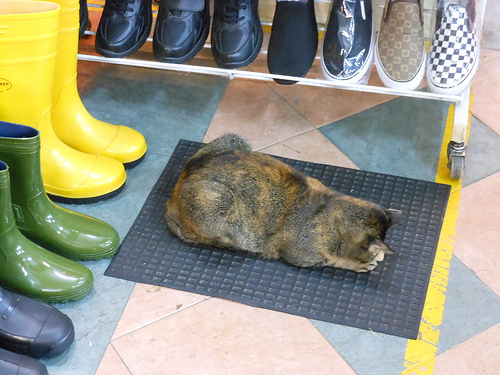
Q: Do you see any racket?
A: No, there are no rackets.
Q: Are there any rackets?
A: No, there are no rackets.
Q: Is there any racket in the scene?
A: No, there are no rackets.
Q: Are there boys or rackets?
A: No, there are no rackets or boys.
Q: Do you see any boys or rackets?
A: No, there are no rackets or boys.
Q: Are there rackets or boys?
A: No, there are no rackets or boys.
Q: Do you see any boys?
A: No, there are no boys.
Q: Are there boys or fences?
A: No, there are no boys or fences.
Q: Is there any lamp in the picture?
A: No, there are no lamps.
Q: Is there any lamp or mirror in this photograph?
A: No, there are no lamps or mirrors.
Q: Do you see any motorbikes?
A: No, there are no motorbikes.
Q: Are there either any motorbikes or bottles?
A: No, there are no motorbikes or bottles.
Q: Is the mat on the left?
A: No, the mat is on the right of the image.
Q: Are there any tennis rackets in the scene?
A: No, there are no tennis rackets.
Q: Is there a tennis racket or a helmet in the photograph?
A: No, there are no rackets or helmets.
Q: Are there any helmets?
A: No, there are no helmets.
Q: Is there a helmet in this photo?
A: No, there are no helmets.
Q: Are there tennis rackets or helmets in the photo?
A: No, there are no helmets or tennis rackets.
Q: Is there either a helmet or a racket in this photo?
A: No, there are no helmets or rackets.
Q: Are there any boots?
A: Yes, there are boots.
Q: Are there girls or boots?
A: Yes, there are boots.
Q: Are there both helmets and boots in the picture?
A: No, there are boots but no helmets.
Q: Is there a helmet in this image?
A: No, there are no helmets.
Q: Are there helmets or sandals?
A: No, there are no helmets or sandals.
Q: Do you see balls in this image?
A: No, there are no balls.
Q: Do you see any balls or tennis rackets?
A: No, there are no balls or tennis rackets.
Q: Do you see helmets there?
A: No, there are no helmets.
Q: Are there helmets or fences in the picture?
A: No, there are no helmets or fences.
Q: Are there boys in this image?
A: No, there are no boys.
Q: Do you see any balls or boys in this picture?
A: No, there are no boys or balls.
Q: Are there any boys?
A: No, there are no boys.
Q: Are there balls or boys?
A: No, there are no boys or balls.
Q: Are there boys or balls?
A: No, there are no boys or balls.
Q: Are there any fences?
A: No, there are no fences.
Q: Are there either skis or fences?
A: No, there are no fences or skis.